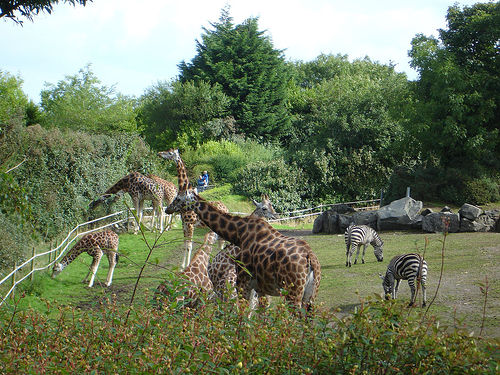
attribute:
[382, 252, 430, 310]
zebra — eating, black, white, grazing, striped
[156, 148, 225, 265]
giraffe — standing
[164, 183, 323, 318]
giraffe — standing, brown, tan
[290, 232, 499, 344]
grass — patchy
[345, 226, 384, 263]
zebra — black, white, grazing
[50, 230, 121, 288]
giraffe — standing, grazing, young, eating, baby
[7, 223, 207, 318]
grass — green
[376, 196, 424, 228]
rock — gray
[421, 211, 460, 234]
rock — gray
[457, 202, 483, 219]
rock — gray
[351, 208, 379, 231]
rock — gray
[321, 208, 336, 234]
rock — gray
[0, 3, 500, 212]
trees — green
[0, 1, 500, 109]
sky — partly cloudy, blue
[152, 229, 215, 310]
giraffe — standing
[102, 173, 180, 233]
giraffe — standing, tall, brown, white, eating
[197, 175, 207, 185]
shirt — blue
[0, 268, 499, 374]
grass — tall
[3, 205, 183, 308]
fence — long, wooden, wood, short, brown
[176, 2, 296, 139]
tree — tall, green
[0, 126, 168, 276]
shrubs — tall, green, large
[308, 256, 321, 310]
tail — brown, tan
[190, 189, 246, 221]
mane — brown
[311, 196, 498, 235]
rocks — piled, gray, large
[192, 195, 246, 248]
neck — outstretched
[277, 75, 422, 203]
bush — green, large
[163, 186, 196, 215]
face — brown, white